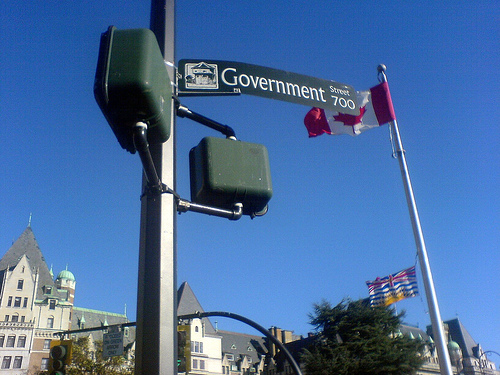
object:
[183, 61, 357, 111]
sign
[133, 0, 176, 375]
pole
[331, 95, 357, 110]
numbers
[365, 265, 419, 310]
flag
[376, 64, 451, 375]
pole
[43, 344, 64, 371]
lights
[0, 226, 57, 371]
buildinbg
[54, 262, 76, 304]
building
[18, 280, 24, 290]
window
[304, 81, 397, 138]
flag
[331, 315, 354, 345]
leavs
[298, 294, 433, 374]
tree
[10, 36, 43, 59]
sky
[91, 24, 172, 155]
signal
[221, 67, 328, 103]
word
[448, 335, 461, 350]
dome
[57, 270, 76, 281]
dome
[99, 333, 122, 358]
sign